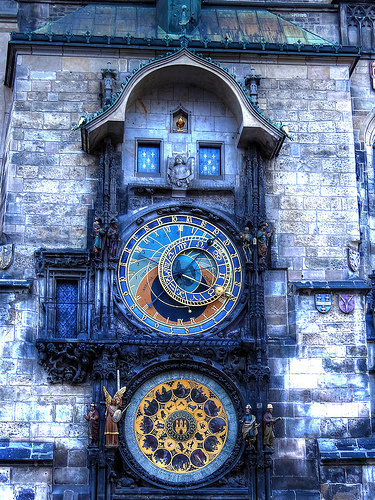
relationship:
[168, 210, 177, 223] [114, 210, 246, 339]
tick of clock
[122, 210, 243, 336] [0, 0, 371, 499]
clock on building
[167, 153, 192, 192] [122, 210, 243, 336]
statuette above clock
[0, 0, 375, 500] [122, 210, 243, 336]
building with clock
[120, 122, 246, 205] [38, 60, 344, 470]
window in a building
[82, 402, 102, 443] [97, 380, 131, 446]
man next to angel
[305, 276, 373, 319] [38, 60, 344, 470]
crest on building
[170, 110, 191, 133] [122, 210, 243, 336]
statuette above clock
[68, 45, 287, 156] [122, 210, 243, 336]
arch above clock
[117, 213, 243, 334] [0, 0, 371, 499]
mechanical calendar on building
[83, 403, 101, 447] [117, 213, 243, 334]
statuettes beside mechanical calendar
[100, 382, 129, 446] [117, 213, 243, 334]
statue beside mechanical calendar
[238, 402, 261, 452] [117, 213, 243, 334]
statuettes beside mechanical calendar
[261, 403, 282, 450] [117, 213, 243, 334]
statuettes beside mechanical calendar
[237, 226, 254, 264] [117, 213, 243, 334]
statuettes beside mechanical calendar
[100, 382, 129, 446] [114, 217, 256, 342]
statue beside clock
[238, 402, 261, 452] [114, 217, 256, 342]
statuettes beside clock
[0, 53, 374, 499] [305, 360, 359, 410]
wall made of brick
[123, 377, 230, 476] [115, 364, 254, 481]
ornaments in clock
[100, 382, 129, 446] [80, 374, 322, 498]
statue in shadow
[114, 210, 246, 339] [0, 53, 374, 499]
clock on wall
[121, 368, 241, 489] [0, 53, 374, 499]
colorful clock on wall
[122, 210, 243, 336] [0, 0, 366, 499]
clock on wall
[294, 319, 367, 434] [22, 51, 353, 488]
bricks on wall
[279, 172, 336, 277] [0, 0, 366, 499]
bricks on wall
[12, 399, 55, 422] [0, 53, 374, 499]
brick on wall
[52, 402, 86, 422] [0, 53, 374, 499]
brick on wall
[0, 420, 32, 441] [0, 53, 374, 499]
brick on wall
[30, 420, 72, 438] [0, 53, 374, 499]
brick on wall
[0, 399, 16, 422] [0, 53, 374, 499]
brick on wall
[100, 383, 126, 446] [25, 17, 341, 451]
statue on outside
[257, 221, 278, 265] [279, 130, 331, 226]
art figure on wall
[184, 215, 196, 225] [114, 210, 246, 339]
tick of a clock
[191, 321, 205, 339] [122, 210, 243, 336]
tick of clock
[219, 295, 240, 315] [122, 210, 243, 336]
tick of clock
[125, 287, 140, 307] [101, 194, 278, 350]
tick of clock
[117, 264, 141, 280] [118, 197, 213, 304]
tick of clock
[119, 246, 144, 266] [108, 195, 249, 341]
tick of clock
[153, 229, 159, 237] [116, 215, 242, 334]
tick of clock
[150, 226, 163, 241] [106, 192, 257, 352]
tick of clock